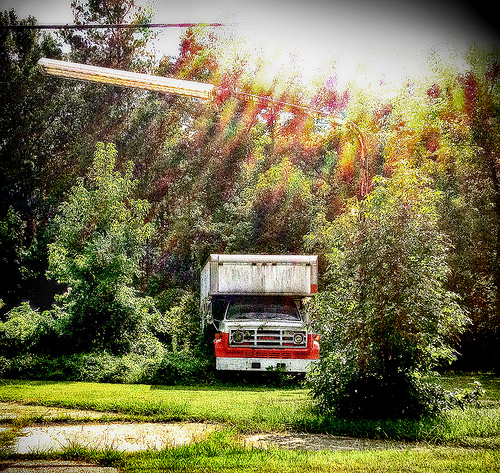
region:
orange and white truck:
[190, 239, 327, 371]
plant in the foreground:
[317, 209, 441, 422]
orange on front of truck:
[220, 328, 316, 368]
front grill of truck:
[232, 325, 302, 345]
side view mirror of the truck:
[202, 298, 216, 325]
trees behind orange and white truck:
[25, 88, 485, 325]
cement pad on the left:
[7, 411, 210, 465]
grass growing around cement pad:
[7, 403, 232, 468]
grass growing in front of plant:
[295, 402, 426, 443]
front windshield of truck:
[224, 295, 295, 321]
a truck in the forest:
[194, 245, 327, 384]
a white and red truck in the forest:
[193, 245, 327, 391]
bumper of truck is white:
[208, 354, 323, 379]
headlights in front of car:
[222, 328, 307, 351]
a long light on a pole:
[20, 50, 233, 113]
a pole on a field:
[337, 116, 388, 421]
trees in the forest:
[3, 0, 498, 465]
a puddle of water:
[16, 402, 222, 462]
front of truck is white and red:
[206, 294, 325, 376]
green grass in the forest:
[5, 368, 498, 465]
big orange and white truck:
[224, 311, 334, 392]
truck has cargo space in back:
[208, 258, 300, 290]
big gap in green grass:
[33, 428, 187, 454]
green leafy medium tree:
[334, 222, 424, 414]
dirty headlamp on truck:
[235, 330, 255, 348]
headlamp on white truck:
[287, 328, 312, 355]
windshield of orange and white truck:
[233, 300, 305, 327]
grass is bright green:
[121, 387, 199, 440]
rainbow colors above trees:
[212, 114, 309, 186]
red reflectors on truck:
[213, 255, 328, 265]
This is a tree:
[78, 142, 174, 385]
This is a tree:
[352, 190, 441, 447]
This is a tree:
[144, 88, 214, 246]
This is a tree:
[446, 90, 498, 365]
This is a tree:
[388, 88, 424, 206]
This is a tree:
[331, 83, 385, 218]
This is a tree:
[11, 28, 50, 235]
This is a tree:
[140, 39, 234, 219]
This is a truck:
[166, 214, 342, 401]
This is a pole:
[42, 49, 398, 176]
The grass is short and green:
[153, 443, 300, 471]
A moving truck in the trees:
[190, 243, 335, 386]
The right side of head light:
[226, 322, 247, 347]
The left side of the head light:
[290, 327, 305, 349]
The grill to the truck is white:
[225, 318, 309, 355]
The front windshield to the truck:
[221, 294, 303, 324]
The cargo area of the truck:
[201, 248, 322, 297]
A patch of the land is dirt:
[23, 418, 204, 452]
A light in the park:
[34, 53, 395, 398]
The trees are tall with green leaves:
[14, 53, 192, 373]